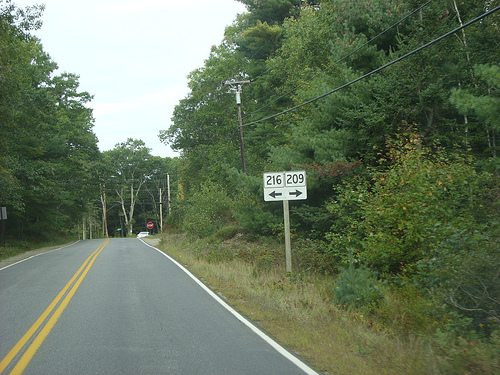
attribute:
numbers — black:
[266, 174, 304, 186]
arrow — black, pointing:
[267, 190, 283, 199]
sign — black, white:
[264, 172, 308, 200]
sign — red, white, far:
[146, 220, 155, 230]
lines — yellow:
[0, 236, 111, 374]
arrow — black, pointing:
[289, 188, 304, 199]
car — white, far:
[136, 231, 152, 239]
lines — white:
[0, 236, 319, 374]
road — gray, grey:
[1, 235, 324, 373]